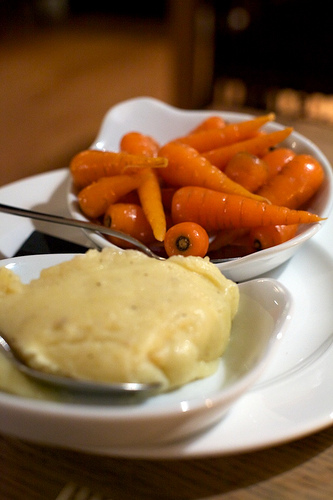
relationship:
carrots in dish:
[68, 108, 330, 259] [62, 107, 333, 284]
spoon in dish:
[0, 325, 168, 402] [62, 107, 333, 284]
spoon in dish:
[0, 200, 259, 266] [62, 107, 333, 284]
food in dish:
[0, 247, 240, 407] [0, 249, 294, 450]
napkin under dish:
[9, 225, 104, 259] [62, 107, 333, 284]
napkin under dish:
[9, 225, 104, 259] [0, 249, 294, 450]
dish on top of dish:
[62, 107, 333, 284] [0, 249, 294, 420]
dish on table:
[0, 249, 294, 420] [1, 103, 331, 498]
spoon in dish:
[0, 325, 168, 402] [0, 249, 294, 450]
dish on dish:
[62, 107, 333, 284] [0, 249, 294, 420]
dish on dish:
[0, 249, 294, 450] [0, 249, 294, 420]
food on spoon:
[0, 247, 240, 407] [0, 325, 168, 402]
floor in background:
[1, 4, 175, 179] [3, 2, 327, 187]